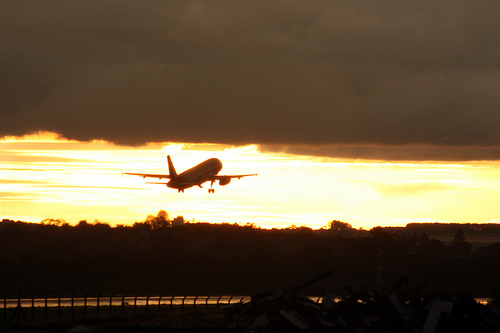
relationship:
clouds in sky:
[0, 0, 499, 160] [0, 0, 500, 226]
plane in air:
[123, 155, 259, 193] [3, 0, 498, 295]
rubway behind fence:
[0, 295, 364, 311] [0, 293, 255, 327]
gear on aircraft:
[166, 180, 216, 193] [123, 155, 259, 193]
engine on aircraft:
[219, 177, 234, 187] [123, 155, 259, 193]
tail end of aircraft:
[167, 154, 176, 178] [123, 155, 259, 193]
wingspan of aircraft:
[122, 167, 257, 184] [123, 155, 259, 193]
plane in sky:
[123, 155, 259, 193] [0, 0, 500, 226]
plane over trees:
[123, 155, 259, 193] [0, 220, 494, 296]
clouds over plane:
[0, 0, 499, 160] [123, 155, 259, 193]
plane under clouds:
[123, 155, 259, 193] [0, 0, 499, 160]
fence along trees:
[0, 293, 255, 327] [0, 220, 494, 296]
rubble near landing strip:
[221, 268, 500, 333] [0, 295, 498, 316]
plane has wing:
[123, 155, 259, 193] [209, 172, 256, 182]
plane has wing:
[123, 155, 259, 193] [122, 171, 178, 181]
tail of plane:
[144, 154, 197, 190] [123, 155, 259, 193]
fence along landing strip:
[0, 293, 255, 327] [0, 295, 498, 316]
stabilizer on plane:
[167, 154, 176, 178] [123, 155, 259, 193]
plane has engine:
[123, 155, 259, 193] [219, 177, 234, 187]